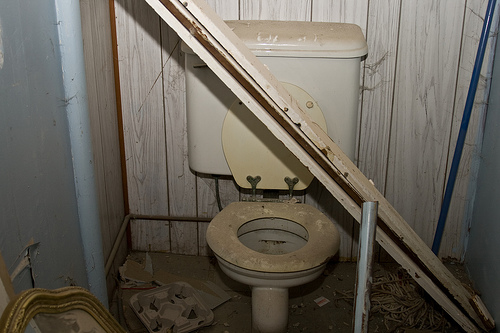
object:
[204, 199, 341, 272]
toilet seat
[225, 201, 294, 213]
dirty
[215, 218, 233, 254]
yellowish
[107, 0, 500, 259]
wall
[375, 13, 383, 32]
white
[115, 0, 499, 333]
wood plank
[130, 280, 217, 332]
cup holder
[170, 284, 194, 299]
brownish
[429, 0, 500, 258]
pole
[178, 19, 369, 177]
toilet tank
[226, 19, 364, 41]
dust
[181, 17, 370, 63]
tank top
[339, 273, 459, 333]
mop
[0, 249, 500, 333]
floor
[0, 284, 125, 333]
picture frame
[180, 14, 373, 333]
toilet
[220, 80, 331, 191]
toilet lid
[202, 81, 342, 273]
up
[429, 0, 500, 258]
blue handle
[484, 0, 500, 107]
corner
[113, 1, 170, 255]
wood paneling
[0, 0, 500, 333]
bathroom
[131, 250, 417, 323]
odd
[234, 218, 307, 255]
toilet bowl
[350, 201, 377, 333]
metal bar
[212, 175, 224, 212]
water pipe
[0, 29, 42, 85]
clean